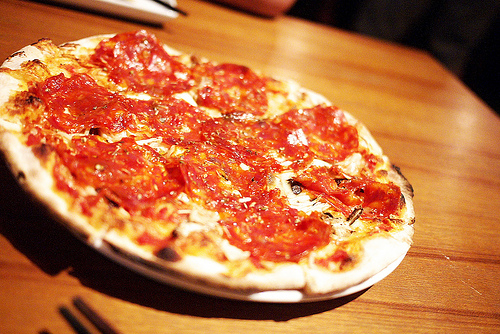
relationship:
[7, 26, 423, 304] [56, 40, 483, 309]
table carrying pizza place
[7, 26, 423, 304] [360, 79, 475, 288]
pizza on table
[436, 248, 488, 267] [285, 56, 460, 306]
dark on table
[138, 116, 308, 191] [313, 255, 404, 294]
pepperoni on plate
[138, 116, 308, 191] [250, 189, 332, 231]
pepperoni and cheese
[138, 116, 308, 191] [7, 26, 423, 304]
pepperoni pizza table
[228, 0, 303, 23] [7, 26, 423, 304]
elbow on table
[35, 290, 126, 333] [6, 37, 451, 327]
silverware on table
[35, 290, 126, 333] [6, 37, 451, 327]
fork on table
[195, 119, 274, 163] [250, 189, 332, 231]
pepporini and cheese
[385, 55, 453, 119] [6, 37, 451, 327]
shine on table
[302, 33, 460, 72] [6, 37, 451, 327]
edge of table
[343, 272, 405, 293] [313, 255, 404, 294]
edge of plate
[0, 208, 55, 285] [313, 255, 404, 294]
shadow of plate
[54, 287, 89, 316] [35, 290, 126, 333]
edge of forks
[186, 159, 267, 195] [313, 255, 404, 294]
small herb plate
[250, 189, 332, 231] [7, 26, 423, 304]
cheese on pizza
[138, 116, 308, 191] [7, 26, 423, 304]
pepperoni on pizza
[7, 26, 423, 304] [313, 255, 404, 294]
pizza on plate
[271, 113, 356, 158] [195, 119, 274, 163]
piece of pepporini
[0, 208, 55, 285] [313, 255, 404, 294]
shadow from plate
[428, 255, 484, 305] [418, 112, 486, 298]
scratch in wood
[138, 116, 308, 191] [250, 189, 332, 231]
pepperoni pizza cheese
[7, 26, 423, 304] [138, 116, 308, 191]
pizza has pepperoni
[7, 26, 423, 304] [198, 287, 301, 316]
pizza on dish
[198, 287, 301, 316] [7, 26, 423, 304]
dish under pizza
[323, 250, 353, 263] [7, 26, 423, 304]
tomato on pizza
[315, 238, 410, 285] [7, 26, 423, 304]
crust on pizza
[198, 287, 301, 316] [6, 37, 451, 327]
dish on table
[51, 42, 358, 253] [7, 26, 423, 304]
top of pizza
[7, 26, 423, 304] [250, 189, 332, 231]
pizza has cheese